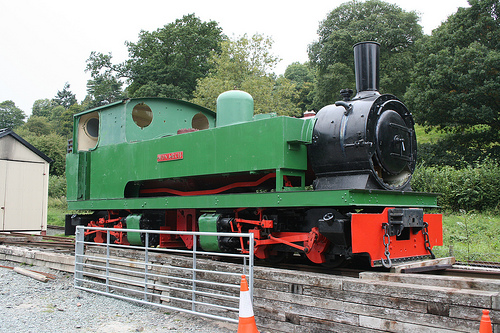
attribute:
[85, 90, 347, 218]
engine — black, green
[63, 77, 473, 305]
train — black, vintage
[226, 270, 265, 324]
cone — traffice, orange, white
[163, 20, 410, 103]
trees — background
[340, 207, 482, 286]
scoop — orange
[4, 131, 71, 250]
station — here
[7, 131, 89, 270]
shed — beige, next, small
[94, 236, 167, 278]
railing — gray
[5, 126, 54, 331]
shack — white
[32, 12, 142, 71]
sky — overhead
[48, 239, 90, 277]
plank — wooden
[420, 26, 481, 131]
tree — dark, behind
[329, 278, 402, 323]
wall — brick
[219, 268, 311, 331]
cones — warning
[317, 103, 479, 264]
locomotive — green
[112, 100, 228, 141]
windows — round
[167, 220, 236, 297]
fence — metal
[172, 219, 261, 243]
rail — silver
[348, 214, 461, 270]
plate — orange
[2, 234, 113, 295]
wood — stacked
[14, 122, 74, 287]
building — white